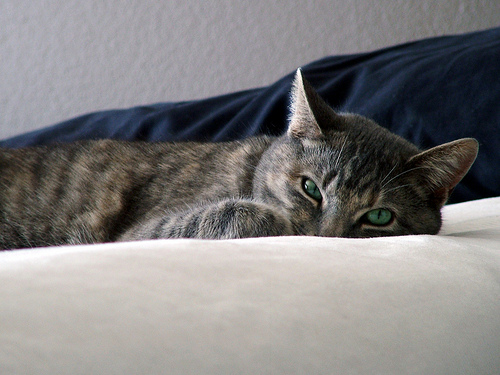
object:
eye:
[295, 170, 328, 206]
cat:
[0, 65, 480, 253]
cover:
[358, 28, 473, 131]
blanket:
[103, 236, 424, 371]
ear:
[283, 65, 338, 140]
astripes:
[74, 149, 151, 229]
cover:
[238, 259, 413, 352]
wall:
[172, 6, 242, 79]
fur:
[181, 153, 219, 191]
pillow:
[357, 67, 431, 91]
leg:
[113, 184, 295, 242]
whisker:
[279, 201, 318, 236]